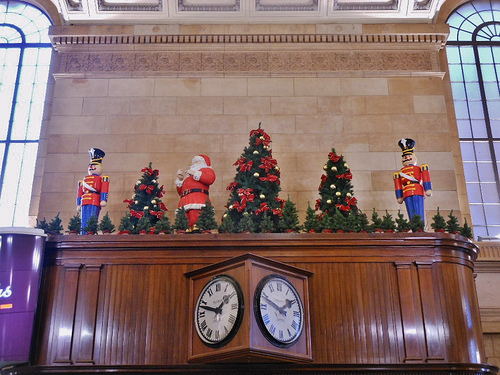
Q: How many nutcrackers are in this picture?
A: Two.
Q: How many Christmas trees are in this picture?
A: Three.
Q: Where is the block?
A: Under the Christmas display.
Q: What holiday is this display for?
A: Christmas.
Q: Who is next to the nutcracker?
A: Santa Claus.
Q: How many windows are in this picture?
A: Two.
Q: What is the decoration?
A: Nutcracker.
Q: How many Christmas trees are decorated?
A: 3.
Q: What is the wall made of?
A: Bricks.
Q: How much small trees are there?
A: Three.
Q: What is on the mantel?
A: A christmas scene.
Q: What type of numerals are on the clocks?
A: Roman numerals.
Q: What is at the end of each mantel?
A: A nutcracker.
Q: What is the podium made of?
A: Wood.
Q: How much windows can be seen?
A: Two.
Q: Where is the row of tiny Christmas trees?
A: The edge of the mantel.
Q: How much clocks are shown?
A: Two.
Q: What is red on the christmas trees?
A: Bows.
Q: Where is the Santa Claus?
A: Between Christmas trees.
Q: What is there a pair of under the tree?
A: Clocks.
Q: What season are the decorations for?
A: Christmas.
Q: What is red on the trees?
A: Bows.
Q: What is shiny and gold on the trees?
A: Balls.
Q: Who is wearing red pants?
A: Santa.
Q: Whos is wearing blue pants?
A: Nutcrackers.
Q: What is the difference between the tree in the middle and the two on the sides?
A: It is bigger.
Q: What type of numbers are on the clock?
A: Roman numerals.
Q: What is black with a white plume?
A: Nutcracker's hat.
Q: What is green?
A: Trees.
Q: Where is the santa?
A: On the shelf.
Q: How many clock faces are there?
A: Two.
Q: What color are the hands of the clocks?
A: Black.